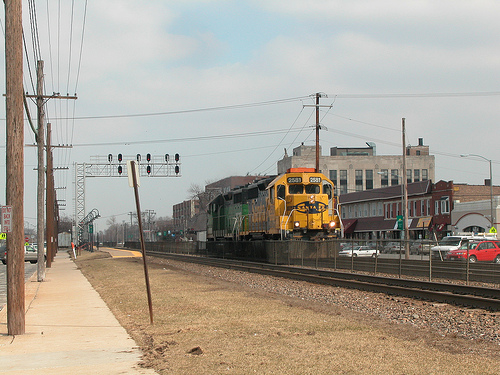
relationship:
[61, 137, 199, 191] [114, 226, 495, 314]
signal structure hanging over tracks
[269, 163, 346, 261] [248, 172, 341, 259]
front of locomotive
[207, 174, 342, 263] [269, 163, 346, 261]
train that painted yellow in front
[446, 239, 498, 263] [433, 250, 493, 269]
car parked in parking spot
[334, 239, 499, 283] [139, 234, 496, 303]
fence separating tracks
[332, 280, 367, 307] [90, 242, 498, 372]
gravel on ground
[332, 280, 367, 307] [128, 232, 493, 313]
gravel lining tracks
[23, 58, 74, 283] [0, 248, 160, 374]
power lines lining cement sidewalk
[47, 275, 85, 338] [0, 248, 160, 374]
cement sidewalk along cement sidewalk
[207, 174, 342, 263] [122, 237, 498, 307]
train on tracks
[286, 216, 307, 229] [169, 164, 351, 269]
front headlight on train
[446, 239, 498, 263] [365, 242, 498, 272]
car in a lot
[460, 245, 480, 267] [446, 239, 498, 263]
front wheel on car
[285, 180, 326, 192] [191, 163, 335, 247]
front windows on train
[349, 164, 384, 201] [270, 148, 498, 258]
windows on building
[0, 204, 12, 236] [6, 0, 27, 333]
letters on pole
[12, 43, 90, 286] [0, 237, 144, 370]
utility poles on sidewalk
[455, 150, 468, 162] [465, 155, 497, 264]
streetlight on pole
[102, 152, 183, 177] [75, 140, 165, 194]
signal structure on structure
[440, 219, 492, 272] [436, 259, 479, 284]
car parked by curb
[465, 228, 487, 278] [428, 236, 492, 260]
car next to car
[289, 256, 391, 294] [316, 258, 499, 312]
fence beside track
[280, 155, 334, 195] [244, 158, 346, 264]
2531 on train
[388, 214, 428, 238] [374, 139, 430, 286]
sign on pole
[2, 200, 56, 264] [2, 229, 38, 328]
sign on pole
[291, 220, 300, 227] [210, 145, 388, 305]
front headlight on train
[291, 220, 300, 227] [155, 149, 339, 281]
front headlight on train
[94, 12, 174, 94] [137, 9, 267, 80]
clouds in sky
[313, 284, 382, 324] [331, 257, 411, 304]
rocks along side train tracks